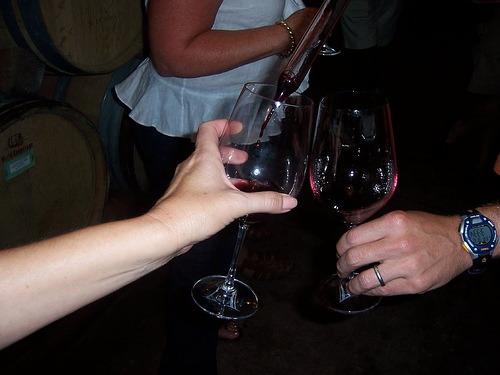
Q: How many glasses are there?
A: Two.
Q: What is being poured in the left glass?
A: Wine.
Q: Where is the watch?
A: On the man's wrist.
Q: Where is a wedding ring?
A: On the man's hand.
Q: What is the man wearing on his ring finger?
A: A wedding ring.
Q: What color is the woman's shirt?
A: White.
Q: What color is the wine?
A: Red.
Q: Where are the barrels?
A: In the back.